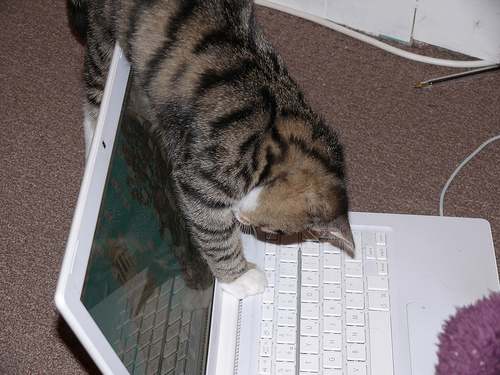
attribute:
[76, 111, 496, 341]
laptop — white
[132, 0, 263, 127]
stripes — black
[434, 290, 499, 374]
object — purple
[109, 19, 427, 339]
cat — white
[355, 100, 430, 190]
carpet — brown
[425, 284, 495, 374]
toy — purple, fuzzy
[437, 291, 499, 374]
fabric — fluffy, purple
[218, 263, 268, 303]
paw — white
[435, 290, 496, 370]
cloth — purple, fuzzy